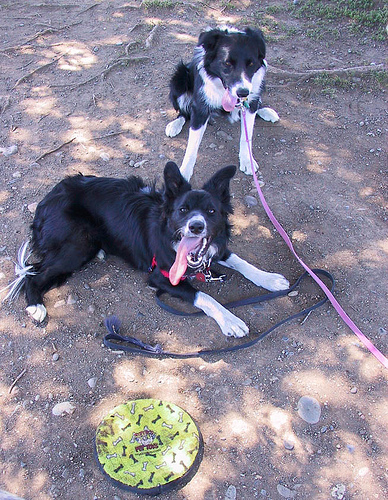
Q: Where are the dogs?
A: On the ground.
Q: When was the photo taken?
A: During daylight hours.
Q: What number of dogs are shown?
A: Two.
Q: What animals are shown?
A: Dogs.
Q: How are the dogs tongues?
A: Wagging.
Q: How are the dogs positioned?
A: Laying and sitting.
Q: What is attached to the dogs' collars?
A: Leashes.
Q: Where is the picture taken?
A: A park.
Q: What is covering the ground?
A: Earth.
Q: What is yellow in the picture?
A: A plate.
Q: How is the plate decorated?
A: With bones.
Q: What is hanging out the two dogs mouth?
A: A tongue.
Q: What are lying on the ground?
A: Two black and white dogs.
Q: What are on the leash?
A: Two dogs.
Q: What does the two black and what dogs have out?
A: Tongue.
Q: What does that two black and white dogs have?
A: Leashes.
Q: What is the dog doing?
A: Sitting down.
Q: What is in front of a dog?
A: A yellow dog toy.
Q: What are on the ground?
A: White rocks.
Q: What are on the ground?
A: A pair of dogs.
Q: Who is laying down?
A: The black and white dogs.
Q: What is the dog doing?
A: Sitting on the ground.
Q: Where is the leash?
A: On the ground,by the dog.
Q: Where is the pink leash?
A: Attached to the dogs collar.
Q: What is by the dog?
A: A dog toy.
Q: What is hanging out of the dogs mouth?
A: Their tongues.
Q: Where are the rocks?
A: Scattered on the ground.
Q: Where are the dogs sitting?
A: In the dirt.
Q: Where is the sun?
A: Reflecting of the ground.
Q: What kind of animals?
A: Dogs.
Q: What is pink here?
A: A leash.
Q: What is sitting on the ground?
A: Dogs.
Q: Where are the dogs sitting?
A: Ground.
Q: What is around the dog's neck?
A: Leashes.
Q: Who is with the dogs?
A: No one.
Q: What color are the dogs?
A: Black and white.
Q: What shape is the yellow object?
A: Round.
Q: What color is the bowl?
A: Yellow.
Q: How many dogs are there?
A: Two.